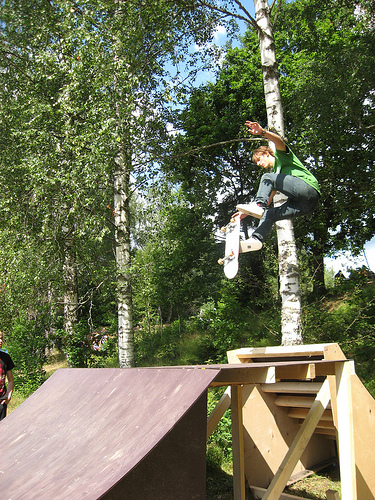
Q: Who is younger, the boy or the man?
A: The boy is younger than the man.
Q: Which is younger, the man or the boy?
A: The boy is younger than the man.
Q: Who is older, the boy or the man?
A: The man is older than the boy.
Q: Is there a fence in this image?
A: No, there are no fences.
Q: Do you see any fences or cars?
A: No, there are no fences or cars.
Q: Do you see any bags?
A: No, there are no bags.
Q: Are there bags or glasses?
A: No, there are no bags or glasses.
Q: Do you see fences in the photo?
A: No, there are no fences.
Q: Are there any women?
A: No, there are no women.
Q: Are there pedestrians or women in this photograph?
A: No, there are no women or pedestrians.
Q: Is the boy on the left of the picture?
A: Yes, the boy is on the left of the image.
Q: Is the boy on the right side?
A: No, the boy is on the left of the image.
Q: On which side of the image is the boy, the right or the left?
A: The boy is on the left of the image.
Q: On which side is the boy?
A: The boy is on the left of the image.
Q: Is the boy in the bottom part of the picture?
A: Yes, the boy is in the bottom of the image.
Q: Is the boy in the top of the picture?
A: No, the boy is in the bottom of the image.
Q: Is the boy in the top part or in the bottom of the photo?
A: The boy is in the bottom of the image.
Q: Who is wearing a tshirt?
A: The boy is wearing a tshirt.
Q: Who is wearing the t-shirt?
A: The boy is wearing a tshirt.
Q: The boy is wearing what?
A: The boy is wearing a t-shirt.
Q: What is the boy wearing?
A: The boy is wearing a t-shirt.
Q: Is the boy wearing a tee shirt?
A: Yes, the boy is wearing a tee shirt.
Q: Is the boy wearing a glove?
A: No, the boy is wearing a tee shirt.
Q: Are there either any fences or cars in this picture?
A: No, there are no fences or cars.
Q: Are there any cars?
A: No, there are no cars.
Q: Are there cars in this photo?
A: No, there are no cars.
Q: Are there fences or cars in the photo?
A: No, there are no cars or fences.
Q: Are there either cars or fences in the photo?
A: No, there are no cars or fences.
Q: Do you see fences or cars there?
A: No, there are no cars or fences.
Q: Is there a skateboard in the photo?
A: Yes, there is a skateboard.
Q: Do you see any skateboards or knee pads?
A: Yes, there is a skateboard.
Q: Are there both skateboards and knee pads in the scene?
A: No, there is a skateboard but no knee pads.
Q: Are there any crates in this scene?
A: No, there are no crates.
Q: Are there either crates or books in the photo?
A: No, there are no crates or books.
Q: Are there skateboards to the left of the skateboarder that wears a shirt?
A: Yes, there is a skateboard to the left of the skateboarder.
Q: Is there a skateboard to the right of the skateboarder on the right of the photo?
A: No, the skateboard is to the left of the skateboarder.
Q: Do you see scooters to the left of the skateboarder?
A: No, there is a skateboard to the left of the skateboarder.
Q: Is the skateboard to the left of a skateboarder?
A: Yes, the skateboard is to the left of a skateboarder.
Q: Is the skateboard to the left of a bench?
A: No, the skateboard is to the left of a skateboarder.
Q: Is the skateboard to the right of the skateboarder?
A: No, the skateboard is to the left of the skateboarder.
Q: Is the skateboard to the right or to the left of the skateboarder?
A: The skateboard is to the left of the skateboarder.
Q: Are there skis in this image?
A: No, there are no skis.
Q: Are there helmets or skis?
A: No, there are no skis or helmets.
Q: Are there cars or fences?
A: No, there are no fences or cars.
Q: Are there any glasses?
A: No, there are no glasses.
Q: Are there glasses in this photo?
A: No, there are no glasses.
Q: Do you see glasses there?
A: No, there are no glasses.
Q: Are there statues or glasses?
A: No, there are no glasses or statues.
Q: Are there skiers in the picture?
A: No, there are no skiers.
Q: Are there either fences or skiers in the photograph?
A: No, there are no skiers or fences.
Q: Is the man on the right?
A: Yes, the man is on the right of the image.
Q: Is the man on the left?
A: No, the man is on the right of the image.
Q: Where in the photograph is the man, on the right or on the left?
A: The man is on the right of the image.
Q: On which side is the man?
A: The man is on the right of the image.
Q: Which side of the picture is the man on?
A: The man is on the right of the image.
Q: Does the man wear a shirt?
A: Yes, the man wears a shirt.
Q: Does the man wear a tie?
A: No, the man wears a shirt.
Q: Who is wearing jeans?
A: The man is wearing jeans.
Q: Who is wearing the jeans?
A: The man is wearing jeans.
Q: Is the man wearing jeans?
A: Yes, the man is wearing jeans.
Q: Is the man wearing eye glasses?
A: No, the man is wearing jeans.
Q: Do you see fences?
A: No, there are no fences.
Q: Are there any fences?
A: No, there are no fences.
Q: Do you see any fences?
A: No, there are no fences.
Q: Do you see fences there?
A: No, there are no fences.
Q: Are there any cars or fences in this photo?
A: No, there are no fences or cars.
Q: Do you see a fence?
A: No, there are no fences.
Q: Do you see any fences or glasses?
A: No, there are no fences or glasses.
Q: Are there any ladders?
A: No, there are no ladders.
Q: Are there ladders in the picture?
A: No, there are no ladders.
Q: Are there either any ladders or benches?
A: No, there are no ladders or benches.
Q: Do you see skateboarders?
A: Yes, there is a skateboarder.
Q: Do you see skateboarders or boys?
A: Yes, there is a skateboarder.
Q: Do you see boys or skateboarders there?
A: Yes, there is a skateboarder.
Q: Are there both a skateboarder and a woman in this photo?
A: No, there is a skateboarder but no women.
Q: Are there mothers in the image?
A: No, there are no mothers.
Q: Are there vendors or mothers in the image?
A: No, there are no mothers or vendors.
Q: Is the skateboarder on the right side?
A: Yes, the skateboarder is on the right of the image.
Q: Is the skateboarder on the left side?
A: No, the skateboarder is on the right of the image.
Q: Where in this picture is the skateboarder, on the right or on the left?
A: The skateboarder is on the right of the image.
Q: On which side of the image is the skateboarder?
A: The skateboarder is on the right of the image.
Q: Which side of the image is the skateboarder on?
A: The skateboarder is on the right of the image.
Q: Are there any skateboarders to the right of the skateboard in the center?
A: Yes, there is a skateboarder to the right of the skateboard.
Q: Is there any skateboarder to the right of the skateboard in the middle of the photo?
A: Yes, there is a skateboarder to the right of the skateboard.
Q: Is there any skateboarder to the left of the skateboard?
A: No, the skateboarder is to the right of the skateboard.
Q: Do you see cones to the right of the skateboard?
A: No, there is a skateboarder to the right of the skateboard.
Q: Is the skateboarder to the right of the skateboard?
A: Yes, the skateboarder is to the right of the skateboard.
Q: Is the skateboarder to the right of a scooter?
A: No, the skateboarder is to the right of the skateboard.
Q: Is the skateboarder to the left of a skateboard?
A: No, the skateboarder is to the right of a skateboard.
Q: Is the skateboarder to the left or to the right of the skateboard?
A: The skateboarder is to the right of the skateboard.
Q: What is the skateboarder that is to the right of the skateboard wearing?
A: The skateboarder is wearing a shirt.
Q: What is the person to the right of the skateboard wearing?
A: The skateboarder is wearing a shirt.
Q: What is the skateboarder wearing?
A: The skateboarder is wearing a shirt.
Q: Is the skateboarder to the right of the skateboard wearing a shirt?
A: Yes, the skateboarder is wearing a shirt.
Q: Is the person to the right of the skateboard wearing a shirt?
A: Yes, the skateboarder is wearing a shirt.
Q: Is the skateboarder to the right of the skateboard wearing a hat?
A: No, the skateboarder is wearing a shirt.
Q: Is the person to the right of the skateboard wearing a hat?
A: No, the skateboarder is wearing a shirt.